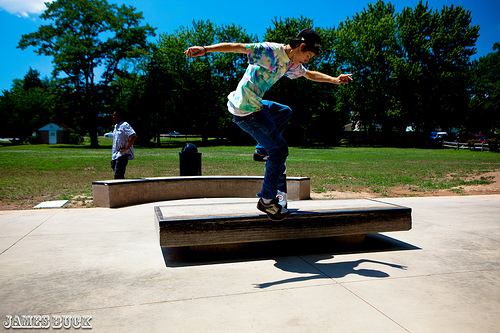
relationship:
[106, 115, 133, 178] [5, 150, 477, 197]
man walking on grass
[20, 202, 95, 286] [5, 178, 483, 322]
cracks in pavement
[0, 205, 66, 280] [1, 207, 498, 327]
cracks in pavement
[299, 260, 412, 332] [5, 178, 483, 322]
cracks in pavement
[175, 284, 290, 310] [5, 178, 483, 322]
cracks in pavement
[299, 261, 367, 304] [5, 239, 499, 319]
cracks in pavement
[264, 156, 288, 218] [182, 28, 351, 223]
skateboard under boy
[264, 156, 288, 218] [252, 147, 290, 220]
skateboard under feet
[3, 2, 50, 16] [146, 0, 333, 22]
cloud in sky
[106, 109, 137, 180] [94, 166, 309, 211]
man behind concrete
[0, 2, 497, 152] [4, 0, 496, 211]
trees along park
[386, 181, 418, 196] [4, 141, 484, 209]
patche along grass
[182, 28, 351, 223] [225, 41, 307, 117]
boy in colorful shirt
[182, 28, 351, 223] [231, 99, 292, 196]
boy in jeans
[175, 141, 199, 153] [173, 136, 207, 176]
top of trashcan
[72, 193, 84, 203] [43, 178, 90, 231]
flowers on ground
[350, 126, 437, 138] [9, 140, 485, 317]
flowers on ground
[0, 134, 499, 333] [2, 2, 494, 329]
ground in park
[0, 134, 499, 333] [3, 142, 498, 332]
ground in park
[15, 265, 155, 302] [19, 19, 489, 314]
ground in park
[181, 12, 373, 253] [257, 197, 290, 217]
boy wearing shoes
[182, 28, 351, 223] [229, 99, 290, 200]
boy wearing jeans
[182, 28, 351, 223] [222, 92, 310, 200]
boy wearing pants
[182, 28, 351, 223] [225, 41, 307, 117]
boy wearing colorful shirt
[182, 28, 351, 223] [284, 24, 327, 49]
boy wearing hat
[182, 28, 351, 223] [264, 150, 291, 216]
boy jumping on skateboard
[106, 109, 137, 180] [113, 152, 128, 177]
man wearing pants